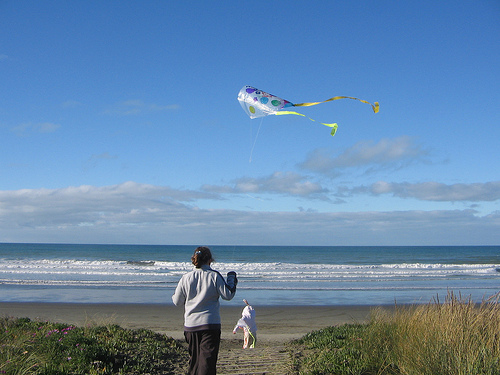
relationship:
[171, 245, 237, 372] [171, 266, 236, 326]
woman wearing shirt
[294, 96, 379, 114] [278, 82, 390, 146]
tail flying horizontally from kite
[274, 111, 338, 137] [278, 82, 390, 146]
tail flying horizontally from kite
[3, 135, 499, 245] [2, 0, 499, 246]
clouds on horizon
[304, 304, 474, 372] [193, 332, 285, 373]
shrubs to left of pathway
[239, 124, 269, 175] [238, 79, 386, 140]
string of kite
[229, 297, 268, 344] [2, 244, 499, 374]
person at beach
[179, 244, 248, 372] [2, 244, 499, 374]
person at beach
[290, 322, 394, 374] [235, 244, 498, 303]
grass beside ocean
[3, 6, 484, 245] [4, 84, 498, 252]
sky covered by clouds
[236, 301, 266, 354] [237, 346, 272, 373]
white dog on sand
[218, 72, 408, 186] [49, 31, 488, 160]
kite flying in air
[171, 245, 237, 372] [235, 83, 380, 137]
woman flying kite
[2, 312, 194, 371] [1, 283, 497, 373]
shrub on beach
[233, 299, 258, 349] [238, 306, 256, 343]
person dressed in cloths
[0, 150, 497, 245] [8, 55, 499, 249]
clouds in sky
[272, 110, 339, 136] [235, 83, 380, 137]
tail on kite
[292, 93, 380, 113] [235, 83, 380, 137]
tail on kite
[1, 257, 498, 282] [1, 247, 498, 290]
cap on wave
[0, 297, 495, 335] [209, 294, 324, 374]
wet sand on shore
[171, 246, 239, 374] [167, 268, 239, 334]
woman in jacket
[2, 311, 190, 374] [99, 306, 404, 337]
grass on dunes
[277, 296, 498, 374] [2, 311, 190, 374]
grass on grass